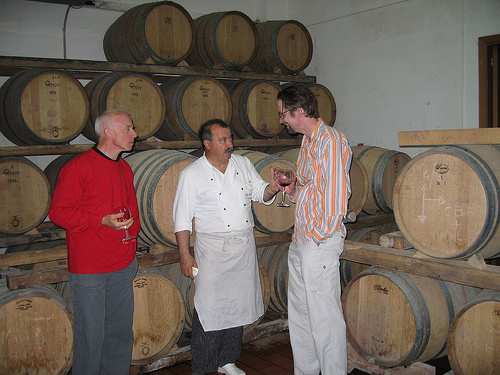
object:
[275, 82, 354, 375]
man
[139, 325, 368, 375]
floor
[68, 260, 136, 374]
grey pants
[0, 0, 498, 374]
winery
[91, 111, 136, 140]
hair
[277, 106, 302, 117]
eye glasses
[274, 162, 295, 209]
glass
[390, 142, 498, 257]
wine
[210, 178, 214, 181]
button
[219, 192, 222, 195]
button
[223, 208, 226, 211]
button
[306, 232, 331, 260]
pocket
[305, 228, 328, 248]
hand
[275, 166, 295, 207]
wine glass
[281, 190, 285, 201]
neck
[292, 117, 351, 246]
shirt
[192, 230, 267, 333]
white apron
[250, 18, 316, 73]
barrels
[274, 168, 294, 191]
wine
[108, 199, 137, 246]
cup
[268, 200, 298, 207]
base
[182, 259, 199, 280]
holding object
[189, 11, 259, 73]
barrels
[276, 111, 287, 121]
glasses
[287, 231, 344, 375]
pants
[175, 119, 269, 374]
man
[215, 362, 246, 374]
foot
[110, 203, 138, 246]
glass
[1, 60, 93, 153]
drum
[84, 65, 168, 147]
drum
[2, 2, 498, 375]
room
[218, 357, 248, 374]
shoe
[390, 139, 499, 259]
barrel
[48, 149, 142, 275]
red shirt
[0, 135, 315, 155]
shelf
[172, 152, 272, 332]
clothes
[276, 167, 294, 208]
cup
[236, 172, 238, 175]
button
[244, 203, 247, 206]
button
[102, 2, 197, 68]
barrel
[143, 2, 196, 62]
base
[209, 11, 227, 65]
strap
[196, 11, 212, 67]
strap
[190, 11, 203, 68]
strap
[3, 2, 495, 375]
cellar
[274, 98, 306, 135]
face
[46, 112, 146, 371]
man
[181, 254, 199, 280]
hand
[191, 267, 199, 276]
object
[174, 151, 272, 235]
shirt